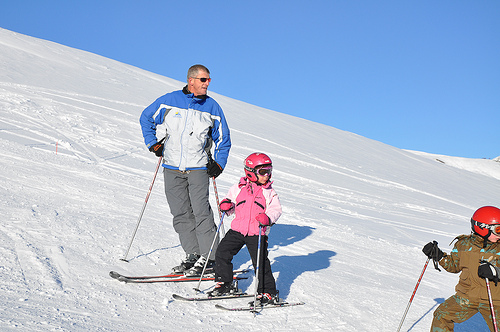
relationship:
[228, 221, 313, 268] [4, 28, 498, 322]
shadow are on ground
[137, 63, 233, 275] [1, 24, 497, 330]
man looking at mountain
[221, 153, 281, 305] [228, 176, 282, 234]
girl wearing ski jacket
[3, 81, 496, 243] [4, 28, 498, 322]
tracks are on snow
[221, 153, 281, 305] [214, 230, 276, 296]
girl wearing ski pants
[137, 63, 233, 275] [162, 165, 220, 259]
man wearing pants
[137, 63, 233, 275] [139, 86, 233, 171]
man wearing jacket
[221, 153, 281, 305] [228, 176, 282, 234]
girl wearing coat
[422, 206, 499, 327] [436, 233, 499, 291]
boy wearing coat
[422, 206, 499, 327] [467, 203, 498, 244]
boy wearing helmet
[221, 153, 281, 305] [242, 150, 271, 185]
girl wearing helmet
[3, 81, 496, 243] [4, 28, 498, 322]
tracks are in snow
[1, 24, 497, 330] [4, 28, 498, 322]
mountain covered with snow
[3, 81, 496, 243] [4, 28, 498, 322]
tracks in snow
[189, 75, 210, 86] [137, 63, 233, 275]
goggles are on man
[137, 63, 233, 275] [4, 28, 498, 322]
man standing on snow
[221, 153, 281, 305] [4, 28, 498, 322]
girl standing on snow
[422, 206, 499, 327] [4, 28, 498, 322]
boy standing on snow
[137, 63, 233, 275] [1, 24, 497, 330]
man on mountain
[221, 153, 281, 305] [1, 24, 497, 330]
girl on mountain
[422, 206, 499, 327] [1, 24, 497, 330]
boy on mountain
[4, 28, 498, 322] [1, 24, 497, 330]
snow covering mountain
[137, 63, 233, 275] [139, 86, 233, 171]
man wearing a jacket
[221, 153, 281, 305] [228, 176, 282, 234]
girl wearing jacket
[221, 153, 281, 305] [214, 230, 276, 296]
girl wearing pants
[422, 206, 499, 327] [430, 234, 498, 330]
boy wearing snow suit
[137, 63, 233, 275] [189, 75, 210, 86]
man wearing goggles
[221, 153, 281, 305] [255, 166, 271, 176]
girl wearing sunglasses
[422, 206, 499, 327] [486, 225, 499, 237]
boy wearing goggles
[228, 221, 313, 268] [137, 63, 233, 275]
shadow behind man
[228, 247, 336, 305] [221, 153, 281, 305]
shadow behind girl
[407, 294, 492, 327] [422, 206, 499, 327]
shadow behind boy